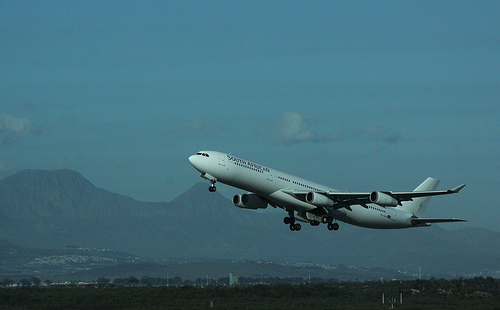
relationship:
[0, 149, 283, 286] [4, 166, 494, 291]
mountians in background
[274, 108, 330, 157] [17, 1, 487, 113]
cloud in sky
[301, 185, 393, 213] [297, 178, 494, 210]
engines on wing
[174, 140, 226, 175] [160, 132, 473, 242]
cockpit of plane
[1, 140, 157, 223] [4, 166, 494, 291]
mountian in background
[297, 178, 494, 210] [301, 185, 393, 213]
wing with jets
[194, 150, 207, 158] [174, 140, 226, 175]
windows in cockpit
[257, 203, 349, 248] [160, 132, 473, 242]
landing gear on airplane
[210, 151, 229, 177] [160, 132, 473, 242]
door on plane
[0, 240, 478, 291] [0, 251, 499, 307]
city in distant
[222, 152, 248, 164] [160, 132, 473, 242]
south on plane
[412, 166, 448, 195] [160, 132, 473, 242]
tail of airplane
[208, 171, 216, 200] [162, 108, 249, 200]
landing gear in front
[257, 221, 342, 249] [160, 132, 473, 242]
rear tires of plane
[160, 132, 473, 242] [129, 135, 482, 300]
plane taking off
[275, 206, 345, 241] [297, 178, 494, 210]
e on wing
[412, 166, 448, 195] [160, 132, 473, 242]
tail of plane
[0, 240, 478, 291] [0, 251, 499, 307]
buildings in distant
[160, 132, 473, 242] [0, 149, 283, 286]
plane in front mountians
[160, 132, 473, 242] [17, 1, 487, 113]
plane in sky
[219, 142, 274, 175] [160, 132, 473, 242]
south american on plane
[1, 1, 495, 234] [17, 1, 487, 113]
fog in sky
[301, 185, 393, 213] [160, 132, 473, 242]
engines on plane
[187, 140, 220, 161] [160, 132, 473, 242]
windshield on plane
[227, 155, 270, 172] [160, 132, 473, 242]
south american on plane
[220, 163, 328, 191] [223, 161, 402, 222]
row of windows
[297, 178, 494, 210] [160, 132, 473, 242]
wing on plane